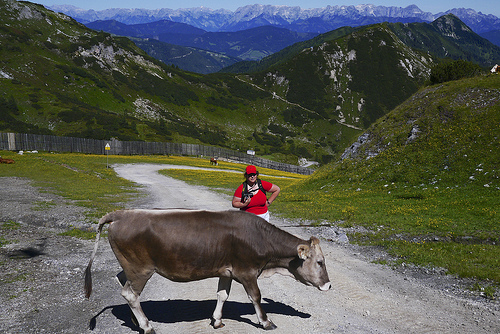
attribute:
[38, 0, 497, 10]
sky — blue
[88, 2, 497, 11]
sky — blue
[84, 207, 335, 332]
cow — brown, white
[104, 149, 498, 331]
path — dirt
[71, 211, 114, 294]
tail — long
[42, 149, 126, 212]
grass — trimmed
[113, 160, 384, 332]
road — dirt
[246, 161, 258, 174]
red hat — red 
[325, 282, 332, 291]
nose — white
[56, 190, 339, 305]
cow — brown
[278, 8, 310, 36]
clouds — white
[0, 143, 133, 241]
area — green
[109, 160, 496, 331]
road — dirt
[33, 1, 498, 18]
sky — blue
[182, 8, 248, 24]
clouds — white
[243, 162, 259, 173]
cap — red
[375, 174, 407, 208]
flowers — yellow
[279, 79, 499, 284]
hill — steep, grass covered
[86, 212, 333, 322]
cow — brown